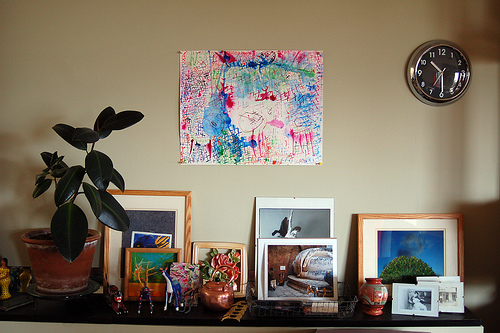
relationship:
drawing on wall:
[178, 47, 325, 168] [2, 1, 497, 332]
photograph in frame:
[377, 232, 446, 278] [359, 213, 464, 277]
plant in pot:
[34, 106, 145, 258] [22, 226, 101, 295]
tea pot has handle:
[197, 266, 238, 313] [211, 266, 237, 284]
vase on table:
[360, 277, 387, 315] [3, 290, 476, 333]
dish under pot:
[25, 279, 99, 299] [22, 226, 101, 295]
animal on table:
[105, 285, 129, 316] [3, 290, 476, 333]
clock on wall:
[404, 36, 473, 109] [2, 1, 497, 332]